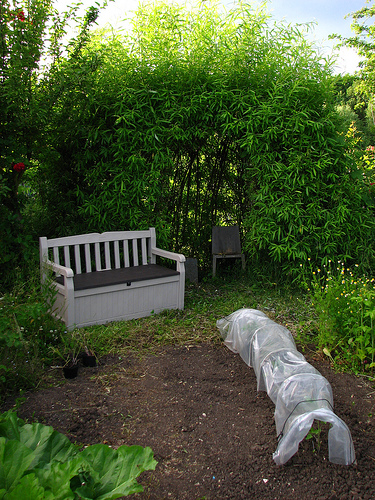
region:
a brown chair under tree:
[211, 221, 247, 278]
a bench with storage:
[36, 227, 186, 333]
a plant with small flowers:
[300, 256, 373, 351]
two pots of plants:
[56, 334, 97, 377]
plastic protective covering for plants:
[214, 304, 356, 465]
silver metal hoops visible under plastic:
[249, 323, 299, 389]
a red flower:
[14, 160, 25, 175]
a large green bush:
[75, 8, 364, 294]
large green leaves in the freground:
[1, 408, 160, 498]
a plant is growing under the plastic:
[307, 416, 328, 458]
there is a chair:
[191, 216, 261, 265]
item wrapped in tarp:
[203, 312, 349, 449]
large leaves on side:
[1, 433, 147, 496]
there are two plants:
[53, 333, 99, 387]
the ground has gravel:
[155, 364, 270, 491]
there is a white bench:
[42, 234, 190, 332]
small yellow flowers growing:
[299, 263, 372, 298]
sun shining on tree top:
[80, 0, 272, 50]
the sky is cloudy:
[304, 0, 337, 46]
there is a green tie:
[276, 390, 345, 416]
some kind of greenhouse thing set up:
[211, 273, 343, 487]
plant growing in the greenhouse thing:
[277, 424, 335, 478]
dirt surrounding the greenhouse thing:
[97, 357, 225, 461]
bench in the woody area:
[0, 223, 195, 340]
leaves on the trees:
[256, 162, 343, 283]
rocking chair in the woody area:
[192, 210, 256, 280]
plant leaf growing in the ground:
[85, 427, 160, 492]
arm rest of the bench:
[141, 237, 182, 267]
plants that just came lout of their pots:
[40, 340, 103, 409]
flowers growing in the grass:
[305, 244, 363, 337]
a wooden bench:
[29, 214, 200, 334]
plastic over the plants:
[211, 302, 355, 479]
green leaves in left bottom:
[0, 426, 161, 498]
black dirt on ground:
[27, 356, 368, 498]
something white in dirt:
[187, 402, 218, 423]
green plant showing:
[293, 416, 343, 464]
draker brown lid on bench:
[54, 256, 186, 289]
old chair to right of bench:
[200, 216, 253, 283]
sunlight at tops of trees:
[75, 6, 295, 77]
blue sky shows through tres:
[240, 0, 372, 68]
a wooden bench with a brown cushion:
[19, 216, 192, 340]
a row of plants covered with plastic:
[218, 294, 349, 463]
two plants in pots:
[49, 331, 105, 385]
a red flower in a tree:
[5, 137, 36, 192]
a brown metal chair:
[205, 216, 249, 277]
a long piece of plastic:
[218, 295, 356, 495]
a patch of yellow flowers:
[307, 263, 361, 320]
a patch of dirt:
[75, 326, 220, 443]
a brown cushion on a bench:
[36, 252, 188, 307]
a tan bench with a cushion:
[32, 222, 190, 335]